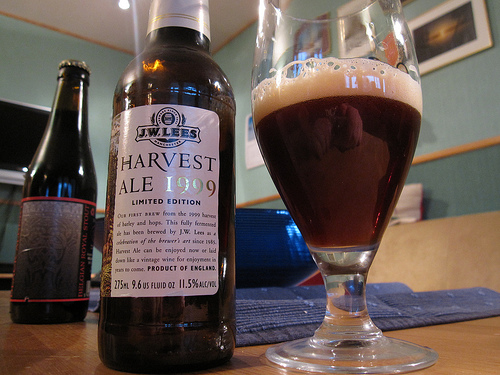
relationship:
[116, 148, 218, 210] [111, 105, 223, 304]
lettering on label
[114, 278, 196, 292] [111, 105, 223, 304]
numbers on label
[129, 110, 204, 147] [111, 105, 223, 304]
logo on label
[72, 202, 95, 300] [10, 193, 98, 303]
letters on label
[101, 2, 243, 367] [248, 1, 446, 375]
bottle next to wine glass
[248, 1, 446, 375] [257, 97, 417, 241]
wine glass containing liquid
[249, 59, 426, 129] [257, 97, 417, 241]
bubbles on liquid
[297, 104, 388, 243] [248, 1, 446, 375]
reflection on wine glass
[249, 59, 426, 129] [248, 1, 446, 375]
bubbles in wine glass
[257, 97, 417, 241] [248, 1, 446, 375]
liquid in wine glass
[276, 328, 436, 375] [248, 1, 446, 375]
base of wine glass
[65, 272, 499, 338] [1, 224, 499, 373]
placemat on table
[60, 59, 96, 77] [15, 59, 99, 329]
top on bottle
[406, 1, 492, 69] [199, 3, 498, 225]
photo on wall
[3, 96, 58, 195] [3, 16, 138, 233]
screen on wall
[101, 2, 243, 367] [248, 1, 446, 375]
bottle beside wine glass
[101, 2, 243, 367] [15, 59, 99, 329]
bottle beside bottle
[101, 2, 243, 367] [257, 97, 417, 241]
bottle beside liquid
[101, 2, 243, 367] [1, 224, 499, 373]
bottle on table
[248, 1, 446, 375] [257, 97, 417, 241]
wine glass with liquid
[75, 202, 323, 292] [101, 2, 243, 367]
bowl behind bottle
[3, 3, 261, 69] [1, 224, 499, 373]
ceiling above table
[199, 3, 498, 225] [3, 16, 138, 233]
wall beside wall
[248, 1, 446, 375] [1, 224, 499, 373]
wine glass on table